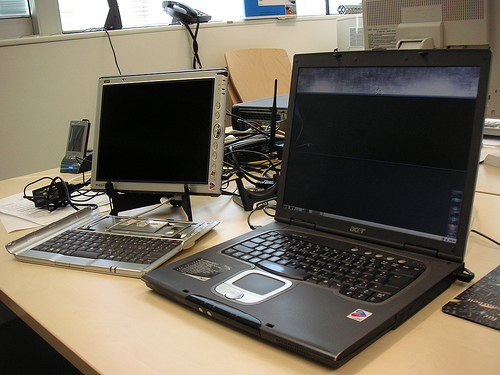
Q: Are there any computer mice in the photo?
A: Yes, there is a computer mouse.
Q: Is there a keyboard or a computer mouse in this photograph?
A: Yes, there is a computer mouse.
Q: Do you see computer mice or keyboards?
A: Yes, there is a computer mouse.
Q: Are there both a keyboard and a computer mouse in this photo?
A: Yes, there are both a computer mouse and a keyboard.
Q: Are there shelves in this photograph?
A: No, there are no shelves.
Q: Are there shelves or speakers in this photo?
A: No, there are no shelves or speakers.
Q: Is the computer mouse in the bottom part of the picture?
A: Yes, the computer mouse is in the bottom of the image.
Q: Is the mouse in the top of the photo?
A: No, the mouse is in the bottom of the image.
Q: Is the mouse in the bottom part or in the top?
A: The mouse is in the bottom of the image.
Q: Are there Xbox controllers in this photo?
A: No, there are no Xbox controllers.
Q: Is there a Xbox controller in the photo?
A: No, there are no Xbox controllers.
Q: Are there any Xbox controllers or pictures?
A: No, there are no Xbox controllers or pictures.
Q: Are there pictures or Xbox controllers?
A: No, there are no Xbox controllers or pictures.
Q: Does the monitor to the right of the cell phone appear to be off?
A: Yes, the monitor is off.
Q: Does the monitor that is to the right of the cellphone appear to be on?
A: No, the monitor is off.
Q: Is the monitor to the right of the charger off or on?
A: The monitor is off.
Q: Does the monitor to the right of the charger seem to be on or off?
A: The monitor is off.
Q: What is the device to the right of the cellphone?
A: The device is a monitor.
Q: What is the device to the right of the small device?
A: The device is a monitor.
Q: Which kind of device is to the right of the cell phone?
A: The device is a monitor.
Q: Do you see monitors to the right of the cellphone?
A: Yes, there is a monitor to the right of the cellphone.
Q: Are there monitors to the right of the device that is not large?
A: Yes, there is a monitor to the right of the cellphone.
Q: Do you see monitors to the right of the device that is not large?
A: Yes, there is a monitor to the right of the cellphone.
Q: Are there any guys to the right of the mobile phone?
A: No, there is a monitor to the right of the mobile phone.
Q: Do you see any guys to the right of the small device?
A: No, there is a monitor to the right of the mobile phone.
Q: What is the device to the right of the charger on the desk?
A: The device is a monitor.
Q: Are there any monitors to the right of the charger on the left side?
A: Yes, there is a monitor to the right of the charger.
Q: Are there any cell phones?
A: Yes, there is a cell phone.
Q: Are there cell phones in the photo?
A: Yes, there is a cell phone.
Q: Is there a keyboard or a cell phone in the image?
A: Yes, there is a cell phone.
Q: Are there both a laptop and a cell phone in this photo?
A: Yes, there are both a cell phone and a laptop.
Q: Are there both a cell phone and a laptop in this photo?
A: Yes, there are both a cell phone and a laptop.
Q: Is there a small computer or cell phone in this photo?
A: Yes, there is a small cell phone.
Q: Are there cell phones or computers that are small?
A: Yes, the cell phone is small.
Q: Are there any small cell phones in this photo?
A: Yes, there is a small cell phone.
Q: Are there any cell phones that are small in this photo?
A: Yes, there is a small cell phone.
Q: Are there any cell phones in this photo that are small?
A: Yes, there is a cell phone that is small.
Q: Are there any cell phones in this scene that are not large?
A: Yes, there is a small cell phone.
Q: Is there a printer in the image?
A: No, there are no printers.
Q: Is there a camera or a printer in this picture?
A: No, there are no printers or cameras.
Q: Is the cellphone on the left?
A: Yes, the cellphone is on the left of the image.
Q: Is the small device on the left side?
A: Yes, the cellphone is on the left of the image.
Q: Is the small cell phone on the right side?
A: No, the mobile phone is on the left of the image.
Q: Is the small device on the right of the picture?
A: No, the mobile phone is on the left of the image.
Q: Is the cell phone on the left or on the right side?
A: The cell phone is on the left of the image.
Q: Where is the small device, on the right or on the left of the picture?
A: The cell phone is on the left of the image.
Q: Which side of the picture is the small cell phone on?
A: The mobile phone is on the left of the image.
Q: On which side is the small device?
A: The mobile phone is on the left of the image.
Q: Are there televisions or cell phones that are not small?
A: No, there is a cell phone but it is small.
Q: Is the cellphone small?
A: Yes, the cellphone is small.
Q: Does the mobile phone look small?
A: Yes, the mobile phone is small.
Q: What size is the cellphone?
A: The cellphone is small.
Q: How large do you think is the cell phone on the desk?
A: The mobile phone is small.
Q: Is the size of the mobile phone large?
A: No, the mobile phone is small.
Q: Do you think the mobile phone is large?
A: No, the mobile phone is small.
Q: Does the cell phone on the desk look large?
A: No, the mobile phone is small.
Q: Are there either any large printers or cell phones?
A: No, there is a cell phone but it is small.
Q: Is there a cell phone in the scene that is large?
A: No, there is a cell phone but it is small.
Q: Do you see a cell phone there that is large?
A: No, there is a cell phone but it is small.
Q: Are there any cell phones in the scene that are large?
A: No, there is a cell phone but it is small.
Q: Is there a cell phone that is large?
A: No, there is a cell phone but it is small.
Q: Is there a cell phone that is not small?
A: No, there is a cell phone but it is small.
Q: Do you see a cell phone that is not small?
A: No, there is a cell phone but it is small.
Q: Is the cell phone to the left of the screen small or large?
A: The cellphone is small.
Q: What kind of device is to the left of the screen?
A: The device is a cell phone.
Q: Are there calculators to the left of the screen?
A: No, there is a cell phone to the left of the screen.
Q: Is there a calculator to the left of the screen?
A: No, there is a cell phone to the left of the screen.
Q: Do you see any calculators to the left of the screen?
A: No, there is a cell phone to the left of the screen.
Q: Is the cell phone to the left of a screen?
A: Yes, the cell phone is to the left of a screen.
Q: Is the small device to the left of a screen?
A: Yes, the cell phone is to the left of a screen.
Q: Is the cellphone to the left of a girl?
A: No, the cellphone is to the left of a screen.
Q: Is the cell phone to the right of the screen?
A: No, the cell phone is to the left of the screen.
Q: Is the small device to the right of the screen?
A: No, the cell phone is to the left of the screen.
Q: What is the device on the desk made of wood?
A: The device is a cell phone.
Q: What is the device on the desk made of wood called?
A: The device is a cell phone.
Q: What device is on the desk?
A: The device is a cell phone.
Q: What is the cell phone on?
A: The cell phone is on the desk.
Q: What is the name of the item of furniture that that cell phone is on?
A: The piece of furniture is a desk.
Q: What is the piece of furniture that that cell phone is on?
A: The piece of furniture is a desk.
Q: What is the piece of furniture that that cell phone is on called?
A: The piece of furniture is a desk.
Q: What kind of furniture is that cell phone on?
A: The cell phone is on the desk.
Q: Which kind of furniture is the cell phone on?
A: The cell phone is on the desk.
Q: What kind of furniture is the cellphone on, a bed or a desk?
A: The cellphone is on a desk.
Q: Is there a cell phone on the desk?
A: Yes, there is a cell phone on the desk.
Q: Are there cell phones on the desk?
A: Yes, there is a cell phone on the desk.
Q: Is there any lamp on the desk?
A: No, there is a cell phone on the desk.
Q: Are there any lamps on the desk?
A: No, there is a cell phone on the desk.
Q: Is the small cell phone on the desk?
A: Yes, the cell phone is on the desk.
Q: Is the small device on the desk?
A: Yes, the cell phone is on the desk.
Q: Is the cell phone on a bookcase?
A: No, the cell phone is on the desk.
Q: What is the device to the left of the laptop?
A: The device is a cell phone.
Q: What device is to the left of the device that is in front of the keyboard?
A: The device is a cell phone.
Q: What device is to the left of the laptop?
A: The device is a cell phone.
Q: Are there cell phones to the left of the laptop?
A: Yes, there is a cell phone to the left of the laptop.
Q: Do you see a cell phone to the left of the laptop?
A: Yes, there is a cell phone to the left of the laptop.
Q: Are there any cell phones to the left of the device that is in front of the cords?
A: Yes, there is a cell phone to the left of the laptop.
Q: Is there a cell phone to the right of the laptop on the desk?
A: No, the cell phone is to the left of the laptop computer.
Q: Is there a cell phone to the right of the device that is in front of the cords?
A: No, the cell phone is to the left of the laptop computer.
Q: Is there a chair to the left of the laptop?
A: No, there is a cell phone to the left of the laptop.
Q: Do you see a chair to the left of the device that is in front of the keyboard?
A: No, there is a cell phone to the left of the laptop.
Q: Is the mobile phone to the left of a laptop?
A: Yes, the mobile phone is to the left of a laptop.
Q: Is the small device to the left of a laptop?
A: Yes, the mobile phone is to the left of a laptop.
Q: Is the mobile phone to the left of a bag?
A: No, the mobile phone is to the left of a laptop.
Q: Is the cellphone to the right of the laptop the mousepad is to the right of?
A: No, the cellphone is to the left of the laptop computer.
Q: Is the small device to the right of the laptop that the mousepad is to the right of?
A: No, the cellphone is to the left of the laptop computer.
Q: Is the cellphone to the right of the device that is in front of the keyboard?
A: No, the cellphone is to the left of the laptop computer.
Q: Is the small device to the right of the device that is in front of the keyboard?
A: No, the cellphone is to the left of the laptop computer.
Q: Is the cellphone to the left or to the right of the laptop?
A: The cellphone is to the left of the laptop.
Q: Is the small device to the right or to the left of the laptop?
A: The cellphone is to the left of the laptop.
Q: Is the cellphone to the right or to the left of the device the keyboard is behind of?
A: The cellphone is to the left of the laptop.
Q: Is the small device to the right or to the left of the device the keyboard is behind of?
A: The cellphone is to the left of the laptop.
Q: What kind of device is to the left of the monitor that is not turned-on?
A: The device is a cell phone.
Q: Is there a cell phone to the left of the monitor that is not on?
A: Yes, there is a cell phone to the left of the monitor.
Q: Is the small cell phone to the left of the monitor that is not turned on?
A: Yes, the cellphone is to the left of the monitor.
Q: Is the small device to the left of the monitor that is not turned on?
A: Yes, the cellphone is to the left of the monitor.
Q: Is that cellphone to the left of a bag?
A: No, the cellphone is to the left of the monitor.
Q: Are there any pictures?
A: No, there are no pictures.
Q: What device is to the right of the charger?
A: The device is a screen.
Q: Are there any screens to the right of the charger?
A: Yes, there is a screen to the right of the charger.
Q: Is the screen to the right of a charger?
A: Yes, the screen is to the right of a charger.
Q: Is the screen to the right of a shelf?
A: No, the screen is to the right of a charger.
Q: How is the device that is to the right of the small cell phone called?
A: The device is a screen.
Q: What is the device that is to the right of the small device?
A: The device is a screen.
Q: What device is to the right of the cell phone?
A: The device is a screen.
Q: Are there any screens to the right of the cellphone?
A: Yes, there is a screen to the right of the cellphone.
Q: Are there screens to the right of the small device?
A: Yes, there is a screen to the right of the cellphone.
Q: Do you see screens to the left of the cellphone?
A: No, the screen is to the right of the cellphone.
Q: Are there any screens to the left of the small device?
A: No, the screen is to the right of the cellphone.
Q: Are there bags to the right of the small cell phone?
A: No, there is a screen to the right of the cell phone.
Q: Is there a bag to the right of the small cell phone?
A: No, there is a screen to the right of the cell phone.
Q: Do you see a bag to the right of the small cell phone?
A: No, there is a screen to the right of the cell phone.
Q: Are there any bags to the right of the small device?
A: No, there is a screen to the right of the cell phone.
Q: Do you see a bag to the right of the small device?
A: No, there is a screen to the right of the cell phone.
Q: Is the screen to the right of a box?
A: No, the screen is to the right of the mobile phone.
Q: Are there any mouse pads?
A: Yes, there is a mouse pad.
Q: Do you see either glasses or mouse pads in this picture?
A: Yes, there is a mouse pad.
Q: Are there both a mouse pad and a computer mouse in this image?
A: Yes, there are both a mouse pad and a computer mouse.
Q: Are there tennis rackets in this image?
A: No, there are no tennis rackets.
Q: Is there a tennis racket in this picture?
A: No, there are no rackets.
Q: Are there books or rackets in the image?
A: No, there are no rackets or books.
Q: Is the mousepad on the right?
A: Yes, the mousepad is on the right of the image.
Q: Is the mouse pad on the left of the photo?
A: No, the mouse pad is on the right of the image.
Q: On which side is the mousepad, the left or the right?
A: The mousepad is on the right of the image.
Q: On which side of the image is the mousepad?
A: The mousepad is on the right of the image.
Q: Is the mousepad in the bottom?
A: Yes, the mousepad is in the bottom of the image.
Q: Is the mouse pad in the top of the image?
A: No, the mouse pad is in the bottom of the image.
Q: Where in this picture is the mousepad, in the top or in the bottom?
A: The mousepad is in the bottom of the image.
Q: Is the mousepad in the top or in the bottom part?
A: The mousepad is in the bottom of the image.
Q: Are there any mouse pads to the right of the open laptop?
A: Yes, there is a mouse pad to the right of the laptop.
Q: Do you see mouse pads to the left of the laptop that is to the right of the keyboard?
A: No, the mouse pad is to the right of the laptop.